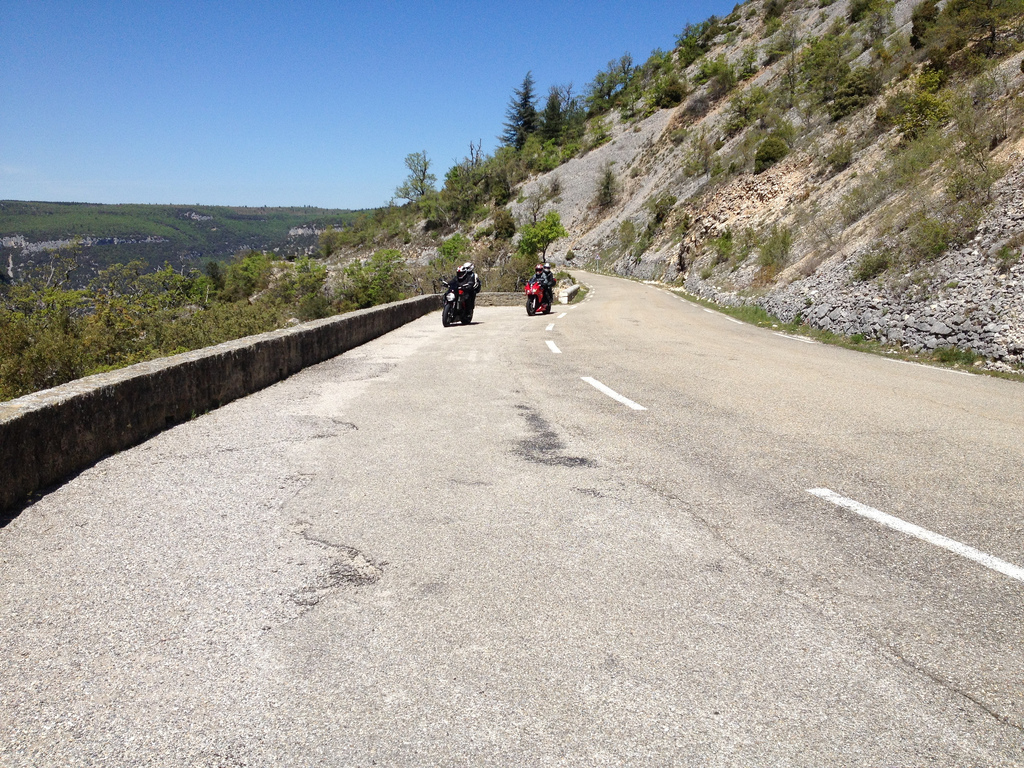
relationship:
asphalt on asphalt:
[14, 206, 1011, 760] [0, 266, 1024, 768]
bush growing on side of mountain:
[854, 231, 899, 279] [334, 13, 1020, 400]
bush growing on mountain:
[890, 217, 958, 272] [334, 13, 1020, 400]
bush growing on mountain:
[949, 160, 998, 209] [314, 16, 988, 386]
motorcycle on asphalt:
[443, 280, 476, 327] [0, 266, 1024, 768]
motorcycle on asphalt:
[521, 278, 557, 316] [0, 266, 1024, 768]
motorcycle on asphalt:
[437, 258, 485, 325] [0, 266, 1024, 768]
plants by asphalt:
[7, 234, 420, 387] [0, 266, 1024, 768]